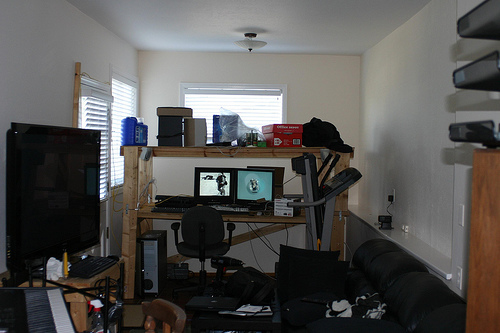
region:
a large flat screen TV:
[1, 119, 101, 284]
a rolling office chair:
[171, 207, 234, 294]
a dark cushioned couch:
[272, 239, 462, 331]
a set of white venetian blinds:
[80, 75, 110, 200]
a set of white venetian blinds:
[109, 70, 140, 188]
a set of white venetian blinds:
[181, 81, 283, 137]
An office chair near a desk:
[170, 208, 235, 288]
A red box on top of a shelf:
[265, 121, 305, 144]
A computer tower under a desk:
[140, 228, 166, 294]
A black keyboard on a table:
[66, 254, 117, 278]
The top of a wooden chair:
[137, 298, 187, 331]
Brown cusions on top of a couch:
[354, 237, 464, 332]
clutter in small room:
[182, 113, 212, 151]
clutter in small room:
[263, 115, 303, 150]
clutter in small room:
[303, 115, 353, 159]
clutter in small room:
[139, 231, 186, 306]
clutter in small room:
[230, 249, 284, 314]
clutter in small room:
[77, 271, 125, 332]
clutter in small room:
[222, 283, 283, 324]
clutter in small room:
[32, 262, 99, 320]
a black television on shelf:
[13, 105, 140, 296]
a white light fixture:
[228, 14, 282, 59]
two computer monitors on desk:
[165, 145, 289, 208]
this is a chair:
[156, 188, 256, 303]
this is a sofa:
[243, 208, 467, 330]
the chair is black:
[151, 192, 251, 320]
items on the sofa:
[305, 265, 392, 330]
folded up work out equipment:
[279, 116, 371, 264]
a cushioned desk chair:
[164, 213, 242, 300]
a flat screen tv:
[2, 68, 134, 275]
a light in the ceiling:
[227, 25, 284, 58]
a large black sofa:
[280, 231, 492, 331]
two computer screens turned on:
[178, 161, 280, 207]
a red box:
[252, 110, 306, 152]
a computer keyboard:
[65, 242, 131, 283]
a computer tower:
[133, 215, 171, 302]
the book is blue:
[117, 116, 162, 151]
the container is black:
[152, 113, 183, 147]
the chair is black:
[175, 191, 230, 275]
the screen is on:
[236, 169, 276, 207]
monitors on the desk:
[192, 167, 280, 201]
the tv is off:
[9, 121, 99, 269]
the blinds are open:
[180, 88, 285, 138]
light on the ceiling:
[233, 36, 266, 51]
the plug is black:
[387, 191, 394, 201]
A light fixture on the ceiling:
[230, 17, 277, 57]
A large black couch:
[284, 240, 460, 328]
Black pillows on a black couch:
[269, 237, 377, 292]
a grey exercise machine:
[279, 146, 370, 253]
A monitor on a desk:
[194, 161, 239, 207]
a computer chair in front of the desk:
[167, 201, 239, 277]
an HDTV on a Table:
[4, 111, 106, 293]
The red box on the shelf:
[257, 118, 312, 153]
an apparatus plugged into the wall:
[374, 184, 403, 236]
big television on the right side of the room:
[7, 123, 107, 249]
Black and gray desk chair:
[183, 210, 228, 262]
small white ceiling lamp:
[234, 31, 266, 53]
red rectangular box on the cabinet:
[265, 123, 310, 148]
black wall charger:
[387, 190, 395, 202]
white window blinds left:
[79, 83, 114, 120]